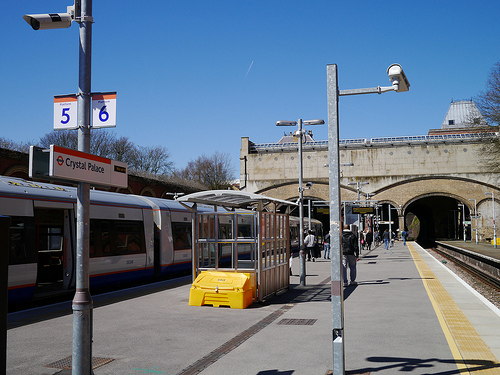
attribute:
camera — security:
[291, 127, 315, 144]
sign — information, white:
[49, 145, 129, 187]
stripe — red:
[51, 141, 115, 166]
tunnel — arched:
[394, 185, 481, 247]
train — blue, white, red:
[3, 112, 352, 366]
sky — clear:
[221, 45, 313, 105]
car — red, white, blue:
[284, 218, 327, 253]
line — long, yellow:
[396, 283, 459, 348]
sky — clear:
[4, 0, 498, 174]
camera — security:
[386, 56, 423, 88]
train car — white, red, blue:
[0, 174, 325, 315]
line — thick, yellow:
[403, 237, 495, 373]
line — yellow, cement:
[401, 239, 489, 374]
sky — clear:
[13, 8, 438, 163]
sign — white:
[47, 142, 129, 190]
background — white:
[90, 90, 122, 128]